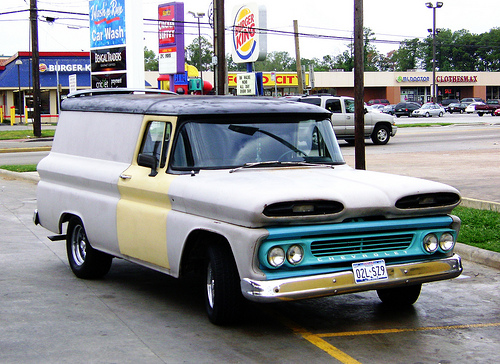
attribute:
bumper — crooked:
[236, 252, 465, 302]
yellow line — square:
[295, 315, 498, 361]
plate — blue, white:
[352, 258, 389, 283]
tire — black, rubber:
[200, 241, 242, 327]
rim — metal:
[204, 267, 215, 311]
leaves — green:
[421, 194, 498, 264]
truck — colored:
[12, 62, 494, 338]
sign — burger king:
[228, 2, 273, 66]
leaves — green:
[263, 48, 300, 73]